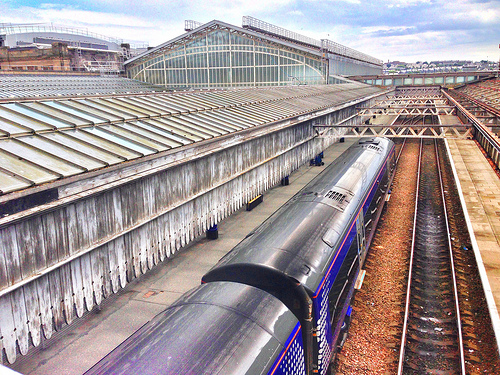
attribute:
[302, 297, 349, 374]
pattern — white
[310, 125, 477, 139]
beam — large, white, metal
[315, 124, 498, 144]
metal beam — large, white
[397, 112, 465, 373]
track — large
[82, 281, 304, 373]
train car — blue, silver, red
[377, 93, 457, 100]
beam — metal, white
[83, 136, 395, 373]
train — silver, passenger, blue, white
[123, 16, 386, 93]
glass building — large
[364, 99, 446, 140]
beam — large, metal, white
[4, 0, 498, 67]
blue sky — bright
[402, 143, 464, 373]
track — railroad, black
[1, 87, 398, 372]
fence — wooden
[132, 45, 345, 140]
metal beam — large, white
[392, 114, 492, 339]
tracks — empty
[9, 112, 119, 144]
metal beam — Large, white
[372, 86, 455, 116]
metal beam — white, large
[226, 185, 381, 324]
train — blue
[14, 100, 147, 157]
metal beam — large, white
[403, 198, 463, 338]
tracks — empty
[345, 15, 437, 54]
clouds — white 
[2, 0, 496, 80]
sky — blue 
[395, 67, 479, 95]
beam — metal, white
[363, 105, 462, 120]
beam — metal, white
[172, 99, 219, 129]
metal beam — large, white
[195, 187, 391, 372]
car — silver blue, red, train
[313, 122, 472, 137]
beam — white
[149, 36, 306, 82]
window — large wall